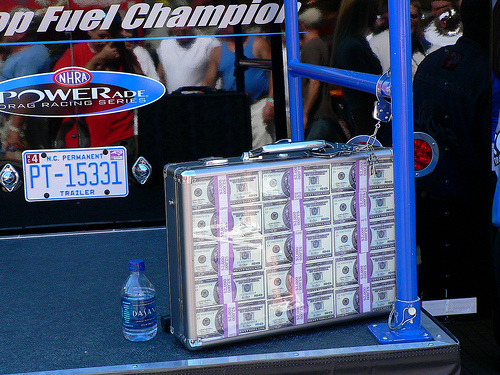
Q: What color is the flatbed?
A: Blue.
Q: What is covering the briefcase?
A: Bills.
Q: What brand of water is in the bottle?
A: Dasani.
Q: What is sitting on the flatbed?
A: A briefcase and a bottle.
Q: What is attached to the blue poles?
A: It's handcuffs.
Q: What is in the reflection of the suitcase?
A: It's people.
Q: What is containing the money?
A: It's money.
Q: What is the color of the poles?
A: It's blue.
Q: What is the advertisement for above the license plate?
A: It's for Powerade.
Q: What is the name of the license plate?
A: It's PT-15331.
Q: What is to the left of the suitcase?
A: It's a bottle of water.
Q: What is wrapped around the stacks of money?
A: Purple paper band.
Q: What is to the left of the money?
A: Water bottle.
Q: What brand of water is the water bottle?
A: Dasani.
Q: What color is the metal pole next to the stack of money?
A: Blue.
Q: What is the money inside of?
A: Briefcase.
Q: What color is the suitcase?
A: Silver.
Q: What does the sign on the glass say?
A: Nhra powerade drag racing series.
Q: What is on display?
A: Money.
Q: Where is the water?
A: Next to the briefcase.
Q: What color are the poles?
A: Blue.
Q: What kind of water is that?
A: Dasani.